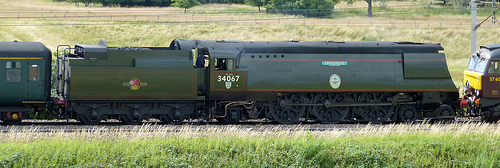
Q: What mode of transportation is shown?
A: A train.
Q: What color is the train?
A: Black.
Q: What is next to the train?
A: Grass.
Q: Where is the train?
A: On the tracks.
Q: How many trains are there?
A: 1.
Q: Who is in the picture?
A: No one.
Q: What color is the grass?
A: Green.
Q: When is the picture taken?
A: Daytime.